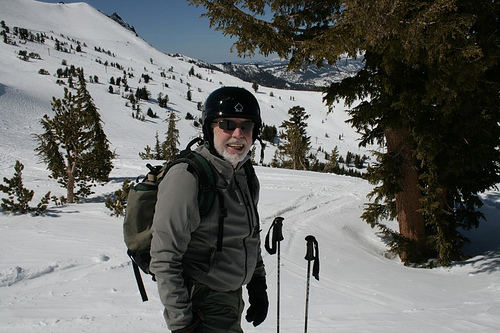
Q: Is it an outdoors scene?
A: Yes, it is outdoors.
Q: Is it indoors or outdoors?
A: It is outdoors.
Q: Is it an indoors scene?
A: No, it is outdoors.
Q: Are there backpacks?
A: Yes, there is a backpack.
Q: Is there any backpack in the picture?
A: Yes, there is a backpack.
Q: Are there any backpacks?
A: Yes, there is a backpack.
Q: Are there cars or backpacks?
A: Yes, there is a backpack.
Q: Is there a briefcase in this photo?
A: No, there are no briefcases.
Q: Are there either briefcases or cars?
A: No, there are no briefcases or cars.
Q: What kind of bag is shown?
A: The bag is a backpack.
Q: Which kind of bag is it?
A: The bag is a backpack.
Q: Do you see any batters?
A: No, there are no batters.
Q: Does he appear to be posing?
A: Yes, the man is posing.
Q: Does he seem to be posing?
A: Yes, the man is posing.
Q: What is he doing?
A: The man is posing.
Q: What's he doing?
A: The man is posing.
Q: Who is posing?
A: The man is posing.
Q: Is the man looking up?
A: No, the man is posing.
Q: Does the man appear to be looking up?
A: No, the man is posing.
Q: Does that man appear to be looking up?
A: No, the man is posing.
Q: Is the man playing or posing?
A: The man is posing.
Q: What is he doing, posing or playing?
A: The man is posing.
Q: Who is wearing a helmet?
A: The man is wearing a helmet.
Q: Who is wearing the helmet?
A: The man is wearing a helmet.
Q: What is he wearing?
A: The man is wearing a helmet.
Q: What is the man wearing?
A: The man is wearing a helmet.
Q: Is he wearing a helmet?
A: Yes, the man is wearing a helmet.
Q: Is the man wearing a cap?
A: No, the man is wearing a helmet.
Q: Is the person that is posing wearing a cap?
A: No, the man is wearing a helmet.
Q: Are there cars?
A: No, there are no cars.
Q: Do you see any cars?
A: No, there are no cars.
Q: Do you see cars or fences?
A: No, there are no cars or fences.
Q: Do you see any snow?
A: Yes, there is snow.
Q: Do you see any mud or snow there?
A: Yes, there is snow.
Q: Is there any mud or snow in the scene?
A: Yes, there is snow.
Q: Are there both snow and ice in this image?
A: No, there is snow but no ice.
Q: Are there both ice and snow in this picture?
A: No, there is snow but no ice.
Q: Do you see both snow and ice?
A: No, there is snow but no ice.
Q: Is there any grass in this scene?
A: No, there is no grass.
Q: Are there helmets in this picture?
A: Yes, there is a helmet.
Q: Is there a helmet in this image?
A: Yes, there is a helmet.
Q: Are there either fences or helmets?
A: Yes, there is a helmet.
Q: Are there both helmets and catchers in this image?
A: No, there is a helmet but no catchers.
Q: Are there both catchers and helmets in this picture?
A: No, there is a helmet but no catchers.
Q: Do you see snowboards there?
A: No, there are no snowboards.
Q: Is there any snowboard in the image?
A: No, there are no snowboards.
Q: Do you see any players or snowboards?
A: No, there are no snowboards or players.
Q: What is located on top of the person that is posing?
A: The helmet is on top of the man.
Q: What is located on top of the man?
A: The helmet is on top of the man.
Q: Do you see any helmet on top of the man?
A: Yes, there is a helmet on top of the man.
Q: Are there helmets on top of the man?
A: Yes, there is a helmet on top of the man.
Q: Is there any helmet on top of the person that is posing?
A: Yes, there is a helmet on top of the man.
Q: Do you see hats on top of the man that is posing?
A: No, there is a helmet on top of the man.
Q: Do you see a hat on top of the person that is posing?
A: No, there is a helmet on top of the man.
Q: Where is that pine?
A: The pine is in the snow.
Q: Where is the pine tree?
A: The pine is in the snow.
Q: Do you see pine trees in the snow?
A: Yes, there is a pine tree in the snow.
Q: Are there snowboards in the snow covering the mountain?
A: No, there is a pine tree in the snow.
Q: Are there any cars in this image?
A: No, there are no cars.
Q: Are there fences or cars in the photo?
A: No, there are no cars or fences.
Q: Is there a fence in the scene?
A: No, there are no fences.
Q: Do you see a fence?
A: No, there are no fences.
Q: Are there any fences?
A: No, there are no fences.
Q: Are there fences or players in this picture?
A: No, there are no fences or players.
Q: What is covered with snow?
A: The mountain is covered with snow.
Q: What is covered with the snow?
A: The mountain is covered with snow.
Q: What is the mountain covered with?
A: The mountain is covered with snow.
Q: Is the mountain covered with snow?
A: Yes, the mountain is covered with snow.